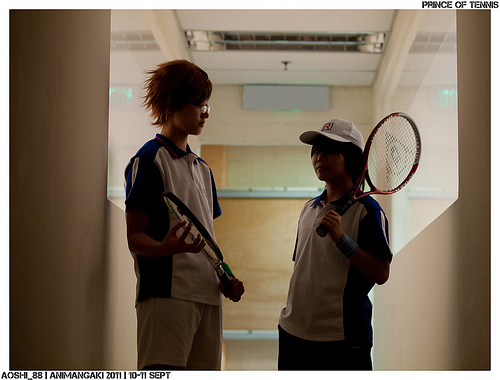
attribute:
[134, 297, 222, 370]
shorts — white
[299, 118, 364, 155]
hat — white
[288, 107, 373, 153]
hat — white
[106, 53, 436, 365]
players — tennis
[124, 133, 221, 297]
jersey — blue, gray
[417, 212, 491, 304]
wall — cream colored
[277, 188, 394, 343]
shirt — white, blue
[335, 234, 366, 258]
wristband — blue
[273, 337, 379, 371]
pant — black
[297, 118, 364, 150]
hat — white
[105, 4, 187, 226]
window — large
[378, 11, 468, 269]
window — large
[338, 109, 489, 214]
racket — tennis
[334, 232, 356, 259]
wristband — gray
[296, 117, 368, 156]
cap — white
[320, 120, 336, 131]
logo — red, black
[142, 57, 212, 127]
hair — brown, red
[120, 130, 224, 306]
shirt — white, blue